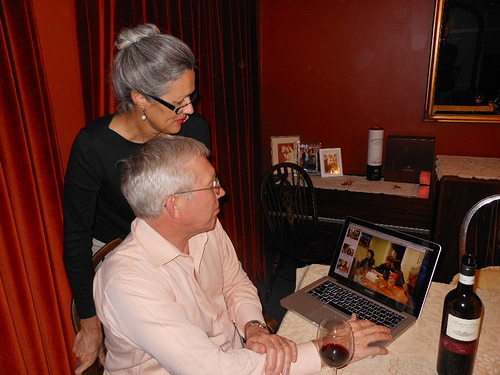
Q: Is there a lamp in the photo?
A: No, there are no lamps.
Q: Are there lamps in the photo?
A: No, there are no lamps.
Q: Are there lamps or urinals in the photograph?
A: No, there are no lamps or urinals.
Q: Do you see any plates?
A: No, there are no plates.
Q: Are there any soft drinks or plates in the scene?
A: No, there are no plates or soft drinks.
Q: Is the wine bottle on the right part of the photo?
A: Yes, the wine bottle is on the right of the image.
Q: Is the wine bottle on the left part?
A: No, the wine bottle is on the right of the image.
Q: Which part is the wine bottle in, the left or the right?
A: The wine bottle is on the right of the image.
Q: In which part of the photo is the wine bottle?
A: The wine bottle is on the right of the image.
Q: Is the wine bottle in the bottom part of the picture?
A: Yes, the wine bottle is in the bottom of the image.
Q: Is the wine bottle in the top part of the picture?
A: No, the wine bottle is in the bottom of the image.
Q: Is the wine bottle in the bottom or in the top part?
A: The wine bottle is in the bottom of the image.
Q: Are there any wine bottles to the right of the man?
A: Yes, there is a wine bottle to the right of the man.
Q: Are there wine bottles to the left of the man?
A: No, the wine bottle is to the right of the man.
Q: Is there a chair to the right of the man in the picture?
A: No, there is a wine bottle to the right of the man.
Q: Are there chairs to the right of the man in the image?
A: No, there is a wine bottle to the right of the man.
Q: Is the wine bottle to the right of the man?
A: Yes, the wine bottle is to the right of the man.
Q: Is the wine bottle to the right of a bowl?
A: No, the wine bottle is to the right of the man.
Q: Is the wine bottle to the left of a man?
A: No, the wine bottle is to the right of a man.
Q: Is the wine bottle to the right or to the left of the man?
A: The wine bottle is to the right of the man.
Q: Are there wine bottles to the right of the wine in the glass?
A: Yes, there is a wine bottle to the right of the wine.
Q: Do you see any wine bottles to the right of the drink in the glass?
A: Yes, there is a wine bottle to the right of the wine.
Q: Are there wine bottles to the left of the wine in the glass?
A: No, the wine bottle is to the right of the wine.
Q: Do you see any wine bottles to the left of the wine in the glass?
A: No, the wine bottle is to the right of the wine.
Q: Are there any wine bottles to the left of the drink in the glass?
A: No, the wine bottle is to the right of the wine.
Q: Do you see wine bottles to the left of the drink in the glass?
A: No, the wine bottle is to the right of the wine.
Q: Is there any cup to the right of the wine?
A: No, there is a wine bottle to the right of the wine.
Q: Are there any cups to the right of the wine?
A: No, there is a wine bottle to the right of the wine.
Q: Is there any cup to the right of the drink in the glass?
A: No, there is a wine bottle to the right of the wine.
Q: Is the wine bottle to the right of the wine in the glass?
A: Yes, the wine bottle is to the right of the wine.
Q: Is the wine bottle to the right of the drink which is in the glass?
A: Yes, the wine bottle is to the right of the wine.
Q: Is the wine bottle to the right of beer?
A: No, the wine bottle is to the right of the wine.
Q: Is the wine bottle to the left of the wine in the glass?
A: No, the wine bottle is to the right of the wine.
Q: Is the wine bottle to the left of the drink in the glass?
A: No, the wine bottle is to the right of the wine.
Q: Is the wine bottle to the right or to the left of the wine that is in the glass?
A: The wine bottle is to the right of the wine.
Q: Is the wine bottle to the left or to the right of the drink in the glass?
A: The wine bottle is to the right of the wine.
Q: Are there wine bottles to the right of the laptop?
A: Yes, there is a wine bottle to the right of the laptop.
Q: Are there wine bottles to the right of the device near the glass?
A: Yes, there is a wine bottle to the right of the laptop.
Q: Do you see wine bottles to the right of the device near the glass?
A: Yes, there is a wine bottle to the right of the laptop.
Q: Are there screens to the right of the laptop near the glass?
A: No, there is a wine bottle to the right of the laptop.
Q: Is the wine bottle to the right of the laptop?
A: Yes, the wine bottle is to the right of the laptop.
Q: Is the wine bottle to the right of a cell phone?
A: No, the wine bottle is to the right of the laptop.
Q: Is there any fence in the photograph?
A: No, there are no fences.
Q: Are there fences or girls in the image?
A: No, there are no fences or girls.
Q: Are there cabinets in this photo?
A: Yes, there is a cabinet.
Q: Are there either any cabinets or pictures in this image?
A: Yes, there is a cabinet.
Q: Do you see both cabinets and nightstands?
A: No, there is a cabinet but no nightstands.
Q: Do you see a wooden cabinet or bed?
A: Yes, there is a wood cabinet.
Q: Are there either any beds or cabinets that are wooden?
A: Yes, the cabinet is wooden.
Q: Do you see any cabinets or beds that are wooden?
A: Yes, the cabinet is wooden.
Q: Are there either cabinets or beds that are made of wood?
A: Yes, the cabinet is made of wood.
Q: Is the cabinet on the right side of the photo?
A: Yes, the cabinet is on the right of the image.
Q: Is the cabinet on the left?
A: No, the cabinet is on the right of the image.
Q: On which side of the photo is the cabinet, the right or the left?
A: The cabinet is on the right of the image.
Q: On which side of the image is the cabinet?
A: The cabinet is on the right of the image.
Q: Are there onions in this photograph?
A: No, there are no onions.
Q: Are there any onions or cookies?
A: No, there are no onions or cookies.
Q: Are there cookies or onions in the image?
A: No, there are no onions or cookies.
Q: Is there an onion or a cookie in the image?
A: No, there are no onions or cookies.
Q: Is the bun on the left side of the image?
A: Yes, the bun is on the left of the image.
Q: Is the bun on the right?
A: No, the bun is on the left of the image.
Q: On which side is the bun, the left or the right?
A: The bun is on the left of the image.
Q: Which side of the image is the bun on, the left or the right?
A: The bun is on the left of the image.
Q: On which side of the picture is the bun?
A: The bun is on the left of the image.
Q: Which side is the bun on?
A: The bun is on the left of the image.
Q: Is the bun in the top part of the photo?
A: Yes, the bun is in the top of the image.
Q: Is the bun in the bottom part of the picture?
A: No, the bun is in the top of the image.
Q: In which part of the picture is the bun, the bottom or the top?
A: The bun is in the top of the image.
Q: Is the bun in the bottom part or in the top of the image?
A: The bun is in the top of the image.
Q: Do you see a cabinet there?
A: Yes, there is a cabinet.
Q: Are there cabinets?
A: Yes, there is a cabinet.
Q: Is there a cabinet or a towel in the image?
A: Yes, there is a cabinet.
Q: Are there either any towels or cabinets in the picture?
A: Yes, there is a cabinet.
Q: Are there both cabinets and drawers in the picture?
A: No, there is a cabinet but no drawers.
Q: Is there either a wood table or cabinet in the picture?
A: Yes, there is a wood cabinet.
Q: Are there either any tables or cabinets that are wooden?
A: Yes, the cabinet is wooden.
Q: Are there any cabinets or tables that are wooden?
A: Yes, the cabinet is wooden.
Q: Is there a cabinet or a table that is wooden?
A: Yes, the cabinet is wooden.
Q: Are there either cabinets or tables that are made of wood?
A: Yes, the cabinet is made of wood.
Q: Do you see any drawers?
A: No, there are no drawers.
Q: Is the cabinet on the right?
A: Yes, the cabinet is on the right of the image.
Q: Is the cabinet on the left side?
A: No, the cabinet is on the right of the image.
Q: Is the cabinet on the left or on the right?
A: The cabinet is on the right of the image.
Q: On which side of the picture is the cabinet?
A: The cabinet is on the right of the image.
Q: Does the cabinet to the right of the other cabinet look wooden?
A: Yes, the cabinet is wooden.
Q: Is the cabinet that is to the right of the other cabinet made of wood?
A: Yes, the cabinet is made of wood.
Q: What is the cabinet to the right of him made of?
A: The cabinet is made of wood.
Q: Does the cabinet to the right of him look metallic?
A: No, the cabinet is wooden.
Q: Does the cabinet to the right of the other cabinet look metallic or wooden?
A: The cabinet is wooden.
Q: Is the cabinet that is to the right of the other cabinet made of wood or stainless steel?
A: The cabinet is made of wood.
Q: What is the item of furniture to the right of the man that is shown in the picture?
A: The piece of furniture is a cabinet.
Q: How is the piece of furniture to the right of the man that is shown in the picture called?
A: The piece of furniture is a cabinet.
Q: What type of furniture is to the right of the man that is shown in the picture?
A: The piece of furniture is a cabinet.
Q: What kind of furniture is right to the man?
A: The piece of furniture is a cabinet.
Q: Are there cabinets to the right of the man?
A: Yes, there is a cabinet to the right of the man.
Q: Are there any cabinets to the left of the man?
A: No, the cabinet is to the right of the man.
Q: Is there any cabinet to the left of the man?
A: No, the cabinet is to the right of the man.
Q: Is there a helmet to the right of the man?
A: No, there is a cabinet to the right of the man.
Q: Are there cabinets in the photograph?
A: Yes, there is a cabinet.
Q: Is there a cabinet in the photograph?
A: Yes, there is a cabinet.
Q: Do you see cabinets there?
A: Yes, there is a cabinet.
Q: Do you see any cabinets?
A: Yes, there is a cabinet.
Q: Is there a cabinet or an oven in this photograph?
A: Yes, there is a cabinet.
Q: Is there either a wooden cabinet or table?
A: Yes, there is a wood cabinet.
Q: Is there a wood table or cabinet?
A: Yes, there is a wood cabinet.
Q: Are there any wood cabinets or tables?
A: Yes, there is a wood cabinet.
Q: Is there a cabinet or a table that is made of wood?
A: Yes, the cabinet is made of wood.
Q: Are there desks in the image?
A: No, there are no desks.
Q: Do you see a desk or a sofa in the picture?
A: No, there are no desks or sofas.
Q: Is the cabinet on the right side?
A: Yes, the cabinet is on the right of the image.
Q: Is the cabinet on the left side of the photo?
A: No, the cabinet is on the right of the image.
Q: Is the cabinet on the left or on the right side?
A: The cabinet is on the right of the image.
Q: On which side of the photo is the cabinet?
A: The cabinet is on the right of the image.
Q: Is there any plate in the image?
A: No, there are no plates.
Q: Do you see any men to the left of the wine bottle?
A: Yes, there is a man to the left of the wine bottle.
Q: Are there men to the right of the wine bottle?
A: No, the man is to the left of the wine bottle.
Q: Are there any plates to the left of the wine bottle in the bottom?
A: No, there is a man to the left of the wine bottle.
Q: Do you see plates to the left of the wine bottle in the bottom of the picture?
A: No, there is a man to the left of the wine bottle.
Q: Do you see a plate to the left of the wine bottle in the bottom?
A: No, there is a man to the left of the wine bottle.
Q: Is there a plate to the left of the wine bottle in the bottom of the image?
A: No, there is a man to the left of the wine bottle.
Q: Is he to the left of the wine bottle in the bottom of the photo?
A: Yes, the man is to the left of the wine bottle.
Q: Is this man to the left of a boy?
A: No, the man is to the left of the wine bottle.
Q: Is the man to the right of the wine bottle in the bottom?
A: No, the man is to the left of the wine bottle.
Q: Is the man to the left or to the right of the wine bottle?
A: The man is to the left of the wine bottle.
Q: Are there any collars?
A: Yes, there is a collar.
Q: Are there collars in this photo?
A: Yes, there is a collar.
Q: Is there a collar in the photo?
A: Yes, there is a collar.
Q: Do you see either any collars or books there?
A: Yes, there is a collar.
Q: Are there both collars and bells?
A: No, there is a collar but no bells.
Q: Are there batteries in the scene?
A: No, there are no batteries.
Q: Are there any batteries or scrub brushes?
A: No, there are no batteries or scrub brushes.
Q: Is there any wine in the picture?
A: Yes, there is wine.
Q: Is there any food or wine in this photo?
A: Yes, there is wine.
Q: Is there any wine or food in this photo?
A: Yes, there is wine.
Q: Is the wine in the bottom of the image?
A: Yes, the wine is in the bottom of the image.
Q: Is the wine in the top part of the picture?
A: No, the wine is in the bottom of the image.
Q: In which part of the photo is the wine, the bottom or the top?
A: The wine is in the bottom of the image.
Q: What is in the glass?
A: The wine is in the glass.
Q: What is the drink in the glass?
A: The drink is wine.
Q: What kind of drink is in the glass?
A: The drink is wine.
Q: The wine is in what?
A: The wine is in the glass.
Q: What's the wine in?
A: The wine is in the glass.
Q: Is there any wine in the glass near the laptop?
A: Yes, there is wine in the glass.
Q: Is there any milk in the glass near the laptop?
A: No, there is wine in the glass.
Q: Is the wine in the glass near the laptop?
A: Yes, the wine is in the glass.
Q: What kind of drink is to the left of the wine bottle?
A: The drink is wine.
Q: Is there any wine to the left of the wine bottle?
A: Yes, there is wine to the left of the wine bottle.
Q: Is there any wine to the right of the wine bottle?
A: No, the wine is to the left of the wine bottle.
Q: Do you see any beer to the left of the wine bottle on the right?
A: No, there is wine to the left of the wine bottle.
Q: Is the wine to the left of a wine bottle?
A: Yes, the wine is to the left of a wine bottle.